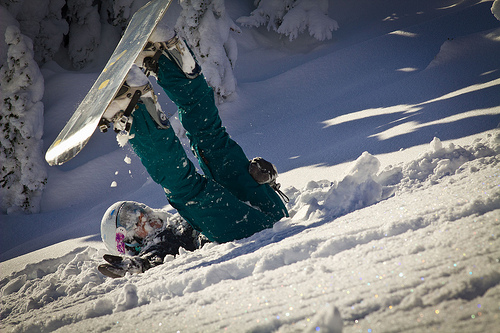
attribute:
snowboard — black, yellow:
[37, 5, 178, 170]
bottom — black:
[45, 0, 162, 167]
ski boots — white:
[105, 75, 170, 146]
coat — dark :
[133, 198, 214, 273]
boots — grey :
[95, 81, 165, 136]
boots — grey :
[137, 44, 187, 81]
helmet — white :
[96, 195, 140, 250]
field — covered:
[330, 148, 462, 205]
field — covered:
[18, 158, 488, 310]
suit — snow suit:
[116, 89, 291, 238]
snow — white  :
[10, 10, 498, 331]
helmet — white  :
[73, 185, 166, 252]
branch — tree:
[175, 0, 245, 104]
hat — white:
[97, 191, 166, 262]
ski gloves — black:
[94, 238, 139, 277]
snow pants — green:
[117, 46, 291, 246]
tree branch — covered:
[233, 0, 346, 44]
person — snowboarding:
[76, 79, 321, 297]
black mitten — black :
[98, 247, 161, 286]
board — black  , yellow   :
[41, 2, 176, 171]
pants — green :
[117, 63, 301, 246]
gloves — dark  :
[97, 157, 277, 277]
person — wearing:
[97, 27, 291, 278]